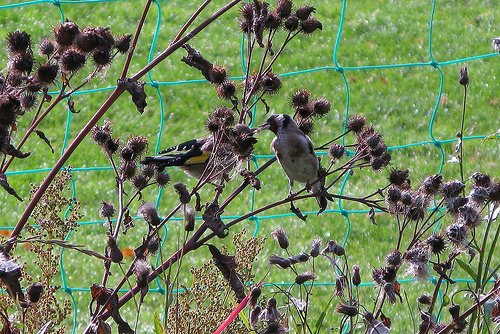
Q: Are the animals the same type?
A: Yes, all the animals are birds.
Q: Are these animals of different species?
A: No, all the animals are birds.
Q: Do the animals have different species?
A: No, all the animals are birds.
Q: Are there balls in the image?
A: Yes, there is a ball.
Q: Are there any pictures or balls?
A: Yes, there is a ball.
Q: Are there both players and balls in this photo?
A: No, there is a ball but no players.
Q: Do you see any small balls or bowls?
A: Yes, there is a small ball.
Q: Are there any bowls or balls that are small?
A: Yes, the ball is small.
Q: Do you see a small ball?
A: Yes, there is a small ball.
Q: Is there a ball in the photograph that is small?
A: Yes, there is a ball that is small.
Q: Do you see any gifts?
A: No, there are no gifts.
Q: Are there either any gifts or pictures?
A: No, there are no gifts or pictures.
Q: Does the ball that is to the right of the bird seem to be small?
A: Yes, the ball is small.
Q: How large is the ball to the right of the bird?
A: The ball is small.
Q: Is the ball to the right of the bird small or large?
A: The ball is small.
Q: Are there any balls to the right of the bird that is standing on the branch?
A: Yes, there is a ball to the right of the bird.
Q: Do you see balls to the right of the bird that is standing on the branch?
A: Yes, there is a ball to the right of the bird.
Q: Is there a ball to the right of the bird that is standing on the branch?
A: Yes, there is a ball to the right of the bird.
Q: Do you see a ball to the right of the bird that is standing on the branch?
A: Yes, there is a ball to the right of the bird.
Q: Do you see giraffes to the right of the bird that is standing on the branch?
A: No, there is a ball to the right of the bird.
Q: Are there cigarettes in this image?
A: No, there are no cigarettes.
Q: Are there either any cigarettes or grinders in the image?
A: No, there are no cigarettes or grinders.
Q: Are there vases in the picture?
A: No, there are no vases.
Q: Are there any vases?
A: No, there are no vases.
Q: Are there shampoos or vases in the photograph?
A: No, there are no vases or shampoos.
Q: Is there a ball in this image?
A: Yes, there is a ball.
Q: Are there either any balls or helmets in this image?
A: Yes, there is a ball.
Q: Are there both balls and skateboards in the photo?
A: No, there is a ball but no skateboards.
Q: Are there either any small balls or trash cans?
A: Yes, there is a small ball.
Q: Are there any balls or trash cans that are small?
A: Yes, the ball is small.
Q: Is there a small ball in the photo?
A: Yes, there is a small ball.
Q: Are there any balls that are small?
A: Yes, there is a ball that is small.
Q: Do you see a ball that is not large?
A: Yes, there is a small ball.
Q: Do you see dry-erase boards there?
A: No, there are no dry-erase boards.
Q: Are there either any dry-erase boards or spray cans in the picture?
A: No, there are no dry-erase boards or spray cans.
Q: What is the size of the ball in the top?
A: The ball is small.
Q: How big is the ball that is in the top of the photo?
A: The ball is small.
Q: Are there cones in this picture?
A: No, there are no cones.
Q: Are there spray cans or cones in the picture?
A: No, there are no cones or spray cans.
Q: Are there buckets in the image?
A: No, there are no buckets.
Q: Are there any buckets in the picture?
A: No, there are no buckets.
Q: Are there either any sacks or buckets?
A: No, there are no buckets or sacks.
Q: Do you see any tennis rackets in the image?
A: No, there are no tennis rackets.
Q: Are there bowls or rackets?
A: No, there are no rackets or bowls.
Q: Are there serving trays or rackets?
A: No, there are no rackets or serving trays.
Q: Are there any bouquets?
A: No, there are no bouquets.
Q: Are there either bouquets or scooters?
A: No, there are no bouquets or scooters.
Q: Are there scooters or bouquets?
A: No, there are no bouquets or scooters.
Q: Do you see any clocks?
A: No, there are no clocks.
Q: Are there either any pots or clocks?
A: No, there are no clocks or pots.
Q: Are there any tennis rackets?
A: No, there are no tennis rackets.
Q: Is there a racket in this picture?
A: No, there are no rackets.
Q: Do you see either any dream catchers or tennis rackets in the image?
A: No, there are no tennis rackets or dream catchers.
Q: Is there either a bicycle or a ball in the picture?
A: Yes, there is a ball.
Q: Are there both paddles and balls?
A: No, there is a ball but no paddles.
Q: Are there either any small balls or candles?
A: Yes, there is a small ball.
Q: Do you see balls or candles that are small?
A: Yes, the ball is small.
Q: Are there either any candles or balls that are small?
A: Yes, the ball is small.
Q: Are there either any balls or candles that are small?
A: Yes, the ball is small.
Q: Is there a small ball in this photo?
A: Yes, there is a small ball.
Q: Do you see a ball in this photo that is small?
A: Yes, there is a ball that is small.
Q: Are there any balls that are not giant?
A: Yes, there is a small ball.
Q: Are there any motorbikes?
A: No, there are no motorbikes.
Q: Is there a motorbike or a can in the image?
A: No, there are no motorcycles or cans.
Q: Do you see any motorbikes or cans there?
A: No, there are no motorbikes or cans.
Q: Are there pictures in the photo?
A: No, there are no pictures.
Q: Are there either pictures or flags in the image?
A: No, there are no pictures or flags.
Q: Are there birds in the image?
A: Yes, there is a bird.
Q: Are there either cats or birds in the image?
A: Yes, there is a bird.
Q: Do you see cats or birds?
A: Yes, there is a bird.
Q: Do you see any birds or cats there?
A: Yes, there is a bird.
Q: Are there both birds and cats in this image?
A: No, there is a bird but no cats.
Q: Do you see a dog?
A: No, there are no dogs.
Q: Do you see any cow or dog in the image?
A: No, there are no dogs or cows.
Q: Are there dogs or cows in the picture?
A: No, there are no dogs or cows.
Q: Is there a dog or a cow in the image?
A: No, there are no dogs or cows.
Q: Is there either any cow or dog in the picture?
A: No, there are no dogs or cows.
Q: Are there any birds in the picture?
A: Yes, there is a bird.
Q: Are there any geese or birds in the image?
A: Yes, there is a bird.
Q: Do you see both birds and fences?
A: Yes, there are both a bird and a fence.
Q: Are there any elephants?
A: No, there are no elephants.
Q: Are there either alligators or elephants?
A: No, there are no elephants or alligators.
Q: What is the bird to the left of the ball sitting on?
A: The bird is sitting on the branch.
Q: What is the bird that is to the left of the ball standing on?
A: The bird is standing on the branch.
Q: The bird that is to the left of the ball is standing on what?
A: The bird is standing on the branch.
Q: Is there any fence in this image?
A: Yes, there is a fence.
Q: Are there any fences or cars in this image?
A: Yes, there is a fence.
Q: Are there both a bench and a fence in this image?
A: No, there is a fence but no benches.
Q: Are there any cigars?
A: No, there are no cigars.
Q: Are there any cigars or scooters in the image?
A: No, there are no cigars or scooters.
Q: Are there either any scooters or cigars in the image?
A: No, there are no cigars or scooters.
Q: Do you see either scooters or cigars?
A: No, there are no cigars or scooters.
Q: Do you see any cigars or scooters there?
A: No, there are no cigars or scooters.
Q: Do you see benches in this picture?
A: No, there are no benches.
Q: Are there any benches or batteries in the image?
A: No, there are no benches or batteries.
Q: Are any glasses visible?
A: No, there are no glasses.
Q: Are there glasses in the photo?
A: No, there are no glasses.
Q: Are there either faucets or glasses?
A: No, there are no glasses or faucets.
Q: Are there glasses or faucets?
A: No, there are no glasses or faucets.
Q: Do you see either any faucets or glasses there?
A: No, there are no glasses or faucets.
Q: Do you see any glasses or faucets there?
A: No, there are no glasses or faucets.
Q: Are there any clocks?
A: No, there are no clocks.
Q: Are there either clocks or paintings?
A: No, there are no clocks or paintings.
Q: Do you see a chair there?
A: No, there are no chairs.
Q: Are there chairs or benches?
A: No, there are no chairs or benches.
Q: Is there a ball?
A: Yes, there is a ball.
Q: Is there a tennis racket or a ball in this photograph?
A: Yes, there is a ball.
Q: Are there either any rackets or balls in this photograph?
A: Yes, there is a ball.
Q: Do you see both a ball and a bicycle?
A: No, there is a ball but no bicycles.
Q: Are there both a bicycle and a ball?
A: No, there is a ball but no bicycles.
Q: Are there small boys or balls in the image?
A: Yes, there is a small ball.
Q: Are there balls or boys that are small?
A: Yes, the ball is small.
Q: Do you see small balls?
A: Yes, there is a small ball.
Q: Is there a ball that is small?
A: Yes, there is a ball that is small.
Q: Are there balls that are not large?
A: Yes, there is a small ball.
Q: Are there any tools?
A: No, there are no tools.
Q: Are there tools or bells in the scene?
A: No, there are no tools or bells.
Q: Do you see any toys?
A: No, there are no toys.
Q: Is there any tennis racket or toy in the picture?
A: No, there are no toys or rackets.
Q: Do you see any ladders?
A: No, there are no ladders.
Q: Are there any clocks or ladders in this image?
A: No, there are no ladders or clocks.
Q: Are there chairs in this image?
A: No, there are no chairs.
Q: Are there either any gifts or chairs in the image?
A: No, there are no chairs or gifts.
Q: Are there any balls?
A: Yes, there is a ball.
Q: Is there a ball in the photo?
A: Yes, there is a ball.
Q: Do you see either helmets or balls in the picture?
A: Yes, there is a ball.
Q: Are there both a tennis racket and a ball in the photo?
A: No, there is a ball but no rackets.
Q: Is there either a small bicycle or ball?
A: Yes, there is a small ball.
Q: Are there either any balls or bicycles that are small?
A: Yes, the ball is small.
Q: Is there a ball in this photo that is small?
A: Yes, there is a ball that is small.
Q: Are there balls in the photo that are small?
A: Yes, there is a ball that is small.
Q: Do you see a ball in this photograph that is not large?
A: Yes, there is a small ball.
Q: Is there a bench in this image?
A: No, there are no benches.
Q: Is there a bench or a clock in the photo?
A: No, there are no benches or clocks.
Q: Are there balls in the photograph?
A: Yes, there is a ball.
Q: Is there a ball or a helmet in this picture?
A: Yes, there is a ball.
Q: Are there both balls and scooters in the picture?
A: No, there is a ball but no scooters.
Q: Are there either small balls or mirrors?
A: Yes, there is a small ball.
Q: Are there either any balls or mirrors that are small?
A: Yes, the ball is small.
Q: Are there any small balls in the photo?
A: Yes, there is a small ball.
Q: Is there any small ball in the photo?
A: Yes, there is a small ball.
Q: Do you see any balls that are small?
A: Yes, there is a ball that is small.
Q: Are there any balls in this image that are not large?
A: Yes, there is a small ball.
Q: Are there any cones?
A: No, there are no cones.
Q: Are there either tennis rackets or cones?
A: No, there are no cones or tennis rackets.